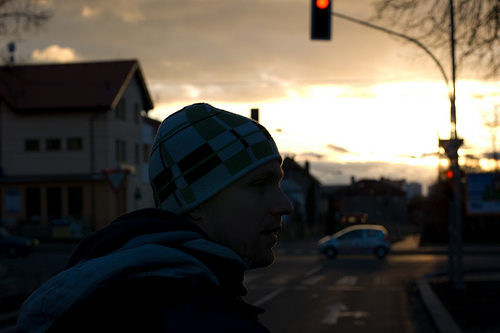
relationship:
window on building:
[66, 140, 81, 157] [2, 56, 159, 261]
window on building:
[74, 186, 90, 233] [2, 56, 154, 237]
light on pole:
[308, 1, 334, 41] [336, 1, 499, 134]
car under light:
[313, 222, 390, 257] [310, 3, 335, 39]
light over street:
[308, 1, 334, 41] [247, 221, 440, 331]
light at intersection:
[308, 1, 334, 41] [256, 227, 466, 331]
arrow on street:
[318, 293, 372, 328] [251, 225, 455, 331]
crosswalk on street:
[253, 268, 414, 295] [247, 221, 440, 331]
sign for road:
[431, 140, 465, 150] [241, 238, 499, 332]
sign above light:
[431, 140, 465, 150] [307, 0, 335, 35]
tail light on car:
[384, 238, 393, 249] [321, 220, 391, 260]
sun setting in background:
[412, 85, 491, 164] [131, 70, 499, 205]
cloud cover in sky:
[16, 4, 499, 94] [3, 6, 498, 183]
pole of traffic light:
[340, 7, 449, 77] [314, 0, 334, 39]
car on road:
[313, 222, 390, 257] [241, 238, 499, 332]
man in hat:
[14, 102, 286, 333] [136, 102, 284, 213]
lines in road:
[226, 265, 415, 295] [241, 238, 499, 332]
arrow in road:
[318, 293, 372, 328] [241, 238, 499, 332]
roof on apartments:
[5, 59, 157, 113] [2, 57, 259, 242]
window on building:
[20, 131, 42, 154] [6, 60, 168, 248]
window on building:
[48, 140, 67, 155] [6, 60, 168, 248]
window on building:
[66, 140, 81, 157] [6, 60, 168, 248]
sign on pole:
[103, 162, 138, 202] [117, 198, 123, 232]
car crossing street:
[313, 222, 390, 257] [243, 216, 445, 326]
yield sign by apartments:
[91, 159, 141, 205] [2, 57, 259, 242]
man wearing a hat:
[78, 51, 299, 329] [133, 99, 268, 205]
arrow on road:
[318, 293, 372, 328] [269, 260, 407, 320]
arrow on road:
[318, 293, 372, 328] [314, 179, 420, 327]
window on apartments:
[20, 127, 60, 166] [2, 57, 259, 242]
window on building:
[23, 192, 44, 225] [2, 56, 154, 237]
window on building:
[135, 102, 142, 125] [2, 56, 154, 237]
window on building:
[132, 140, 141, 165] [2, 56, 154, 237]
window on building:
[109, 132, 127, 167] [2, 56, 154, 237]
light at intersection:
[308, 1, 334, 41] [243, 238, 416, 281]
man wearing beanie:
[14, 102, 286, 333] [145, 101, 284, 217]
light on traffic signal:
[308, 1, 334, 41] [309, 0, 452, 134]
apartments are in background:
[2, 57, 314, 303] [20, 186, 480, 316]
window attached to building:
[111, 90, 135, 126] [10, 50, 172, 218]